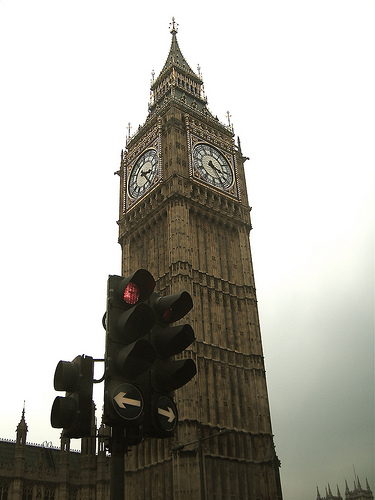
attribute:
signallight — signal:
[50, 268, 197, 498]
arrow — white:
[111, 388, 143, 411]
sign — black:
[112, 380, 178, 434]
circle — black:
[110, 383, 144, 417]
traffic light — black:
[50, 353, 92, 437]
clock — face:
[120, 134, 163, 205]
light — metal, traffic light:
[109, 265, 146, 311]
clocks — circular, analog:
[192, 139, 237, 188]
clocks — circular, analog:
[120, 150, 156, 198]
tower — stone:
[0, 11, 281, 496]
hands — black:
[208, 161, 220, 173]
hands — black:
[208, 157, 225, 186]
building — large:
[6, 14, 302, 499]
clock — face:
[191, 141, 235, 190]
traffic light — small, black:
[48, 350, 98, 444]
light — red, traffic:
[104, 274, 187, 376]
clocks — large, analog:
[118, 144, 243, 197]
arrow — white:
[158, 405, 176, 423]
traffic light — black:
[35, 248, 206, 455]